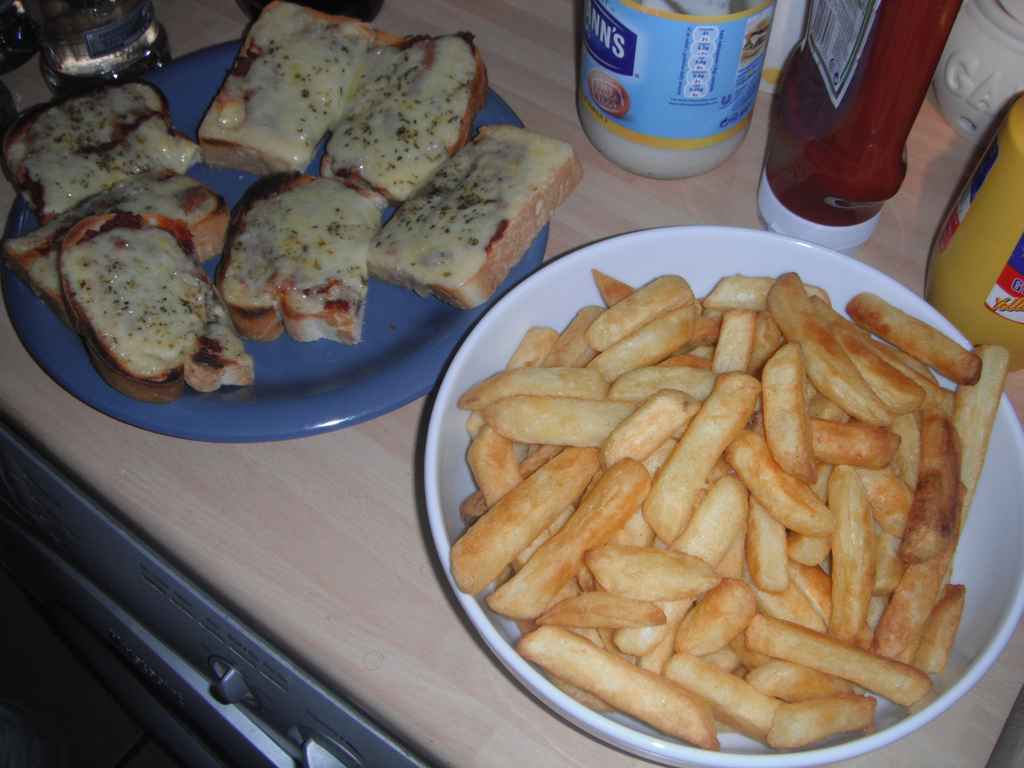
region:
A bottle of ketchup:
[779, 12, 917, 234]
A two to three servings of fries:
[566, 322, 889, 681]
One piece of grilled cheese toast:
[210, 184, 375, 352]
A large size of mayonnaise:
[574, 9, 756, 165]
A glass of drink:
[24, 3, 162, 80]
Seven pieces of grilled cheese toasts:
[14, 7, 553, 419]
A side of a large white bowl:
[991, 552, 1021, 674]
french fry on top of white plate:
[579, 273, 692, 352]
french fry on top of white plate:
[582, 298, 702, 380]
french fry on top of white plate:
[456, 366, 613, 409]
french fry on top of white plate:
[602, 390, 706, 466]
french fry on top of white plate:
[763, 338, 821, 487]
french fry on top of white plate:
[765, 272, 895, 429]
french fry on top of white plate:
[843, 286, 979, 385]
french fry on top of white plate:
[675, 581, 751, 659]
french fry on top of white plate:
[912, 582, 962, 676]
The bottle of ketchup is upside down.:
[758, 0, 970, 254]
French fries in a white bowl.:
[411, 218, 1022, 766]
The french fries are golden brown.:
[446, 263, 1016, 751]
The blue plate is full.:
[6, 6, 577, 449]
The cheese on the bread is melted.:
[54, 202, 261, 412]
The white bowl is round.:
[414, 217, 1022, 767]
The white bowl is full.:
[419, 220, 1023, 767]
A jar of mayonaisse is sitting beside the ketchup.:
[575, 0, 972, 261]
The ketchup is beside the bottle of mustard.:
[757, 2, 1023, 391]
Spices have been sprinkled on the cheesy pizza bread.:
[2, 2, 585, 445]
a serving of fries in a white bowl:
[421, 226, 1020, 762]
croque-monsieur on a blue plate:
[0, 0, 589, 447]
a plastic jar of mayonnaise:
[580, 0, 774, 178]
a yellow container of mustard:
[923, 94, 1022, 366]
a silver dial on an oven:
[203, 656, 257, 718]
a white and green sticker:
[803, 0, 883, 115]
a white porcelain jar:
[934, 4, 1021, 144]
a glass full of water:
[14, 2, 170, 92]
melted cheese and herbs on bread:
[201, 2, 489, 200]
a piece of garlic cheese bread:
[60, 210, 253, 401]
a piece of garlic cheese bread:
[218, 166, 381, 345]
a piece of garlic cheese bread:
[367, 124, 582, 311]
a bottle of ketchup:
[752, 0, 962, 250]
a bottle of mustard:
[928, 92, 1023, 372]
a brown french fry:
[517, 625, 721, 749]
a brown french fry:
[667, 652, 781, 739]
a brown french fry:
[767, 696, 876, 745]